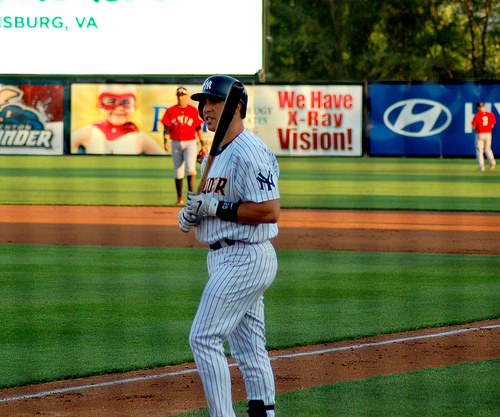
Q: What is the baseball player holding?
A: A bat.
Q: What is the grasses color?
A: Green.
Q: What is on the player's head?
A: A helmet.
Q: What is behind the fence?
A: Trees.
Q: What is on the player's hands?
A: Gloves.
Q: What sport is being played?
A: Baseball.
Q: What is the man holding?
A: Baseball bat.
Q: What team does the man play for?
A: Yankees.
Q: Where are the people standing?
A: On the field.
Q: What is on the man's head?
A: Helmet.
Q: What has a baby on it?
A: Billboard sign.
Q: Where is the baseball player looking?
A: To the left.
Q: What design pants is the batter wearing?
A: Striped.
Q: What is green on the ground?
A: The grass.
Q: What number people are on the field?
A: Three.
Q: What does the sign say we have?
A: X-ray vision.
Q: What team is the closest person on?
A: Yankees.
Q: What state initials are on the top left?
A: Virginia.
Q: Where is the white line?
A: Down base line.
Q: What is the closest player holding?
A: Bat.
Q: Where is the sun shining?
A: Outfield.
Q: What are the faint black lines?
A: Fence between player and photographer.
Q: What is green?
A: Grass.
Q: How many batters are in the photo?
A: One.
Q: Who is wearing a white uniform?
A: Batter.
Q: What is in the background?
A: Trees.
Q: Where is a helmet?
A: On batter's head.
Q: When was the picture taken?
A: Daytime.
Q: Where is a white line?
A: On the dirt.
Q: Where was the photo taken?
A: At a baseball game.